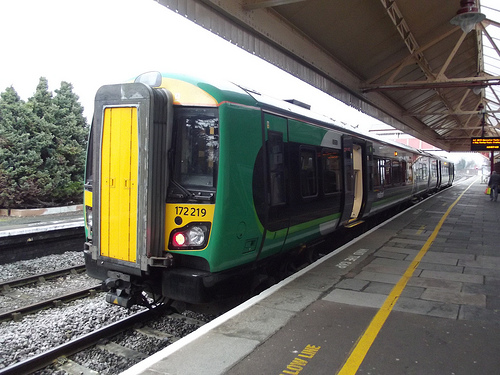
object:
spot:
[292, 349, 298, 353]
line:
[338, 178, 479, 375]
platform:
[118, 181, 499, 375]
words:
[290, 357, 308, 366]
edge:
[115, 186, 454, 375]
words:
[201, 208, 208, 217]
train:
[80, 68, 455, 314]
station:
[115, 0, 500, 375]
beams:
[359, 2, 500, 93]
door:
[348, 139, 365, 220]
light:
[169, 224, 207, 248]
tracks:
[1, 261, 170, 375]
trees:
[1, 75, 56, 211]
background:
[0, 47, 500, 190]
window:
[174, 116, 219, 186]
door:
[91, 83, 153, 272]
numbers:
[174, 206, 208, 217]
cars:
[439, 157, 458, 188]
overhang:
[151, 2, 498, 153]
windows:
[299, 144, 321, 197]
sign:
[468, 137, 500, 152]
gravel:
[1, 252, 217, 375]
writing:
[485, 145, 499, 149]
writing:
[336, 247, 368, 270]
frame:
[385, 70, 497, 115]